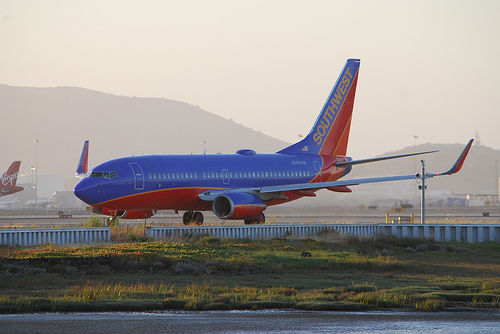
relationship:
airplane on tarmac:
[73, 58, 475, 225] [3, 211, 493, 231]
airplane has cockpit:
[73, 58, 475, 225] [85, 171, 111, 181]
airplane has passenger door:
[66, 46, 486, 241] [120, 163, 150, 192]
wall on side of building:
[2, 227, 109, 243] [3, 206, 497, 252]